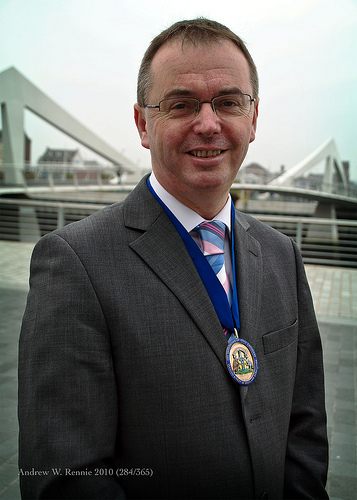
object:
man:
[17, 13, 330, 499]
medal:
[146, 177, 258, 386]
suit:
[17, 170, 330, 500]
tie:
[197, 222, 233, 313]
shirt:
[145, 172, 231, 238]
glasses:
[144, 93, 256, 124]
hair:
[151, 18, 246, 54]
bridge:
[0, 63, 148, 245]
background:
[0, 0, 356, 192]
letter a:
[18, 469, 26, 478]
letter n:
[24, 471, 29, 478]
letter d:
[31, 467, 38, 479]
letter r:
[34, 469, 40, 477]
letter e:
[37, 469, 42, 477]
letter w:
[50, 467, 61, 479]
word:
[63, 467, 92, 482]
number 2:
[94, 468, 99, 477]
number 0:
[99, 468, 104, 476]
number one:
[104, 468, 108, 476]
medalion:
[225, 339, 258, 386]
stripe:
[201, 221, 226, 257]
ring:
[234, 328, 240, 339]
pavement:
[301, 255, 356, 499]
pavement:
[0, 244, 34, 499]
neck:
[151, 161, 232, 226]